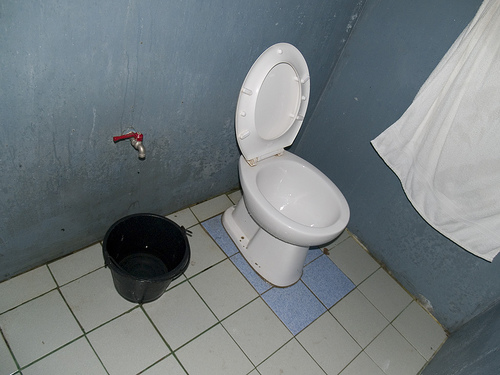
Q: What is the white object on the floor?
A: Toilet.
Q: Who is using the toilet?
A: No one.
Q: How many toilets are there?
A: One.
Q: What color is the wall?
A: Blue.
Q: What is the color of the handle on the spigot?
A: Red.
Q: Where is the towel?
A: On the wall.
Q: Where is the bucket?
A: Near the toilet.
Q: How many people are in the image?
A: None.